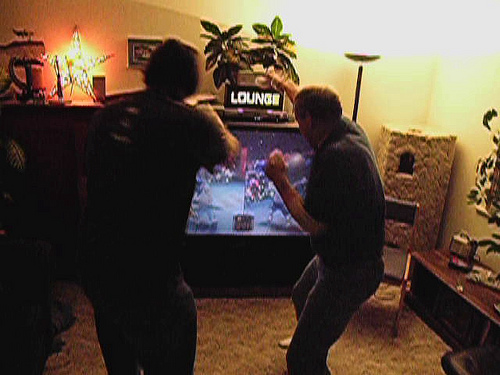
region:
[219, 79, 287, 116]
black sign with white writing that says 'lounge'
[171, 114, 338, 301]
large screened television with video game projected on it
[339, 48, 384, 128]
black metal floor lamp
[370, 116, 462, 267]
light tan colored carpeted cat tower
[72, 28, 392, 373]
two men standing in front of television playing wii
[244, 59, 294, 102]
video game controller on man's hand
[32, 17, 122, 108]
illuminated star on shelf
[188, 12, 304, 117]
green large leafed house plant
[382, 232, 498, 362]
dark brown colored wooden tale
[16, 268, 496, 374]
tan colored shag carpet in living room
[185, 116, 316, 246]
large flat screen TV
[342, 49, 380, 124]
black floor lamp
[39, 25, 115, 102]
glowing decorative star light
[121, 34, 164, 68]
picture hanging on a wall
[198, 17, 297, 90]
plant on top of the TV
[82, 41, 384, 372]
two people playing a game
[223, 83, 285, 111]
"Lounge" sign on top of a TV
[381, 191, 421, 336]
chair next to a TV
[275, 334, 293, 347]
man wearing white socks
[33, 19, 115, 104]
Lit star sitting on table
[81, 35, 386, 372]
Two men standing in front of tv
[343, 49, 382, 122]
Black light lit in the corner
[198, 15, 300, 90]
Plants sitting on top of tv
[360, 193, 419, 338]
Wooden chair sitting on floor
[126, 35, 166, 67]
Picture on the wall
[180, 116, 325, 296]
Large tv in middle of room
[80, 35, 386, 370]
Two men playing video games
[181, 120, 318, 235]
Video game showing on tv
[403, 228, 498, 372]
Table with knick knacks next to wall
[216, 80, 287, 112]
a lighted lounge sign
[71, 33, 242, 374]
a man standing in front of the TV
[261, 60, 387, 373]
a man standing in front of the TV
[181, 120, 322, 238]
a TV with a video game on it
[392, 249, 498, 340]
a small table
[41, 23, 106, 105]
a lighted white star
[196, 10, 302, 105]
house plants located on top of TV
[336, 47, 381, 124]
a floor lamp that is turned on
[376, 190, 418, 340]
a chair located next to the TV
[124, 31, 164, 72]
a picture located on the wall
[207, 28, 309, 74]
Green plant on top of tv.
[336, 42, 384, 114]
Black floor lamp in room.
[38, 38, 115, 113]
Lite up star on shelf.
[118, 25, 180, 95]
Framed picture on wall.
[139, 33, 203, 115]
Person has dark hair.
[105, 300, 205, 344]
Person wearing dark pants.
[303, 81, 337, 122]
Person has short hair.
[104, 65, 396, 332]
Two people playing the wii game.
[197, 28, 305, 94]
A plant on top of the television.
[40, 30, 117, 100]
Light shining against the wall.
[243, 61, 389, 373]
man standing in front of television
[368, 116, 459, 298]
cat playhouse in corner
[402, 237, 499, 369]
coffee table against wall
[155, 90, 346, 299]
large television by wall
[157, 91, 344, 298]
television by wall is large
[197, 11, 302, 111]
green plant on television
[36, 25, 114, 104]
lit up star on wall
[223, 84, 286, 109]
a black and white lounge sign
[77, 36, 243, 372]
a man playing Wii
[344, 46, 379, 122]
a black ornamental lamp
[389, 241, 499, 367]
a wooden side table